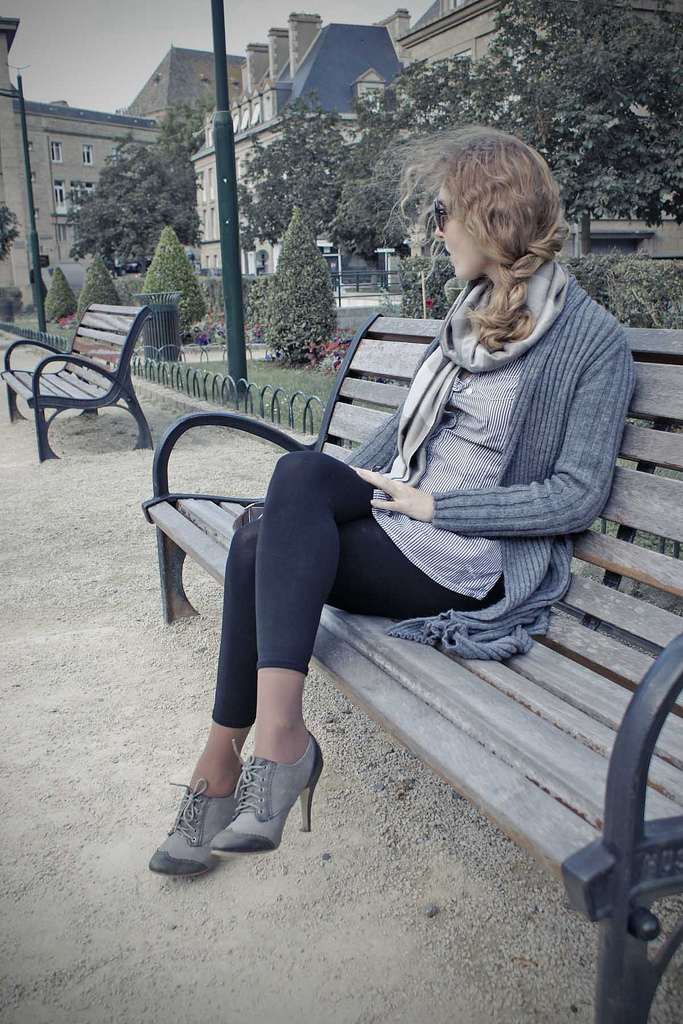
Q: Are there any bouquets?
A: No, there are no bouquets.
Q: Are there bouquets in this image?
A: No, there are no bouquets.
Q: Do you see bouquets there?
A: No, there are no bouquets.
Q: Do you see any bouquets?
A: No, there are no bouquets.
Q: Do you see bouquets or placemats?
A: No, there are no bouquets or placemats.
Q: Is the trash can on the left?
A: Yes, the trash can is on the left of the image.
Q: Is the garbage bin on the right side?
A: No, the garbage bin is on the left of the image.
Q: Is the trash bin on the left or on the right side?
A: The trash bin is on the left of the image.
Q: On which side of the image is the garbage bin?
A: The garbage bin is on the left of the image.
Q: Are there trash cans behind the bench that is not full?
A: Yes, there is a trash can behind the bench.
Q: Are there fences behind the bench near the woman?
A: No, there is a trash can behind the bench.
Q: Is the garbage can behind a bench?
A: Yes, the garbage can is behind a bench.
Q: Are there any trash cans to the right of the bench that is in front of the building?
A: Yes, there is a trash can to the right of the bench.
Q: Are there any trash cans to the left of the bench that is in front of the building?
A: No, the trash can is to the right of the bench.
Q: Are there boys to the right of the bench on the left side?
A: No, there is a trash can to the right of the bench.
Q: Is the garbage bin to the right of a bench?
A: Yes, the garbage bin is to the right of a bench.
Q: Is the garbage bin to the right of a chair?
A: No, the garbage bin is to the right of a bench.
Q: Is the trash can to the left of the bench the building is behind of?
A: No, the trash can is to the right of the bench.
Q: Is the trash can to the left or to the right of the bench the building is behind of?
A: The trash can is to the right of the bench.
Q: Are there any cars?
A: No, there are no cars.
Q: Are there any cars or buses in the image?
A: No, there are no cars or buses.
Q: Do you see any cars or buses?
A: No, there are no cars or buses.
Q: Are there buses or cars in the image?
A: No, there are no cars or buses.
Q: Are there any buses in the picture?
A: No, there are no buses.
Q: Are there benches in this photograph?
A: Yes, there is a bench.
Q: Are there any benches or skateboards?
A: Yes, there is a bench.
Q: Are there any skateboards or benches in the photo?
A: Yes, there is a bench.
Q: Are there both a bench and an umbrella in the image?
A: No, there is a bench but no umbrellas.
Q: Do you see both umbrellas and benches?
A: No, there is a bench but no umbrellas.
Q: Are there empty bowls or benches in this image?
A: Yes, there is an empty bench.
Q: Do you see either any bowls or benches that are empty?
A: Yes, the bench is empty.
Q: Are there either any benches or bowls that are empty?
A: Yes, the bench is empty.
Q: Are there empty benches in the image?
A: Yes, there is an empty bench.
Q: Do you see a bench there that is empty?
A: Yes, there is a bench that is empty.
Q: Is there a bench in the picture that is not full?
A: Yes, there is a empty bench.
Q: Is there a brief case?
A: No, there are no briefcases.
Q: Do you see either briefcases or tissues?
A: No, there are no briefcases or tissues.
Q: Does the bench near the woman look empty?
A: Yes, the bench is empty.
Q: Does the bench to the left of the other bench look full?
A: No, the bench is empty.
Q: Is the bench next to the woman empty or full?
A: The bench is empty.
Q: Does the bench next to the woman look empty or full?
A: The bench is empty.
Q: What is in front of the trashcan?
A: The bench is in front of the trashcan.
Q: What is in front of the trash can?
A: The bench is in front of the trashcan.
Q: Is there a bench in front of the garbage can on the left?
A: Yes, there is a bench in front of the trash can.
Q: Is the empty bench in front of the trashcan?
A: Yes, the bench is in front of the trashcan.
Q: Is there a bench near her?
A: Yes, there is a bench near the woman.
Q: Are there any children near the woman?
A: No, there is a bench near the woman.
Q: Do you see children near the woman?
A: No, there is a bench near the woman.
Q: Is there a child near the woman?
A: No, there is a bench near the woman.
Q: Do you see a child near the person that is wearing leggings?
A: No, there is a bench near the woman.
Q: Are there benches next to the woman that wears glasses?
A: Yes, there is a bench next to the woman.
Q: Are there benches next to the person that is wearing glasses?
A: Yes, there is a bench next to the woman.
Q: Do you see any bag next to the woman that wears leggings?
A: No, there is a bench next to the woman.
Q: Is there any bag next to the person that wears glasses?
A: No, there is a bench next to the woman.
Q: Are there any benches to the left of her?
A: Yes, there is a bench to the left of the woman.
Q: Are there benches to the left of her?
A: Yes, there is a bench to the left of the woman.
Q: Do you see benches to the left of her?
A: Yes, there is a bench to the left of the woman.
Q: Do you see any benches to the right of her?
A: No, the bench is to the left of the woman.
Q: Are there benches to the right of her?
A: No, the bench is to the left of the woman.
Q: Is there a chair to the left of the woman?
A: No, there is a bench to the left of the woman.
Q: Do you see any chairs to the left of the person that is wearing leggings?
A: No, there is a bench to the left of the woman.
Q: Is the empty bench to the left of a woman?
A: Yes, the bench is to the left of a woman.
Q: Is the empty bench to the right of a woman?
A: No, the bench is to the left of a woman.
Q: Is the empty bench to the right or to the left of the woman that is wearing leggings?
A: The bench is to the left of the woman.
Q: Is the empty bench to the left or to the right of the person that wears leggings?
A: The bench is to the left of the woman.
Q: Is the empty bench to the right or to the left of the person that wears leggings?
A: The bench is to the left of the woman.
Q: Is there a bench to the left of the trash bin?
A: Yes, there is a bench to the left of the trash bin.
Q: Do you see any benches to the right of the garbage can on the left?
A: No, the bench is to the left of the trashcan.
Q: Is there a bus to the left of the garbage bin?
A: No, there is a bench to the left of the garbage bin.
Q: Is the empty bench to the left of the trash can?
A: Yes, the bench is to the left of the trash can.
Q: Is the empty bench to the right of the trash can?
A: No, the bench is to the left of the trash can.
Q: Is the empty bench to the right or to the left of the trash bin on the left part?
A: The bench is to the left of the trash bin.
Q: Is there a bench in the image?
A: Yes, there is a bench.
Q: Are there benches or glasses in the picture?
A: Yes, there is a bench.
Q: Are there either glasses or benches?
A: Yes, there is a bench.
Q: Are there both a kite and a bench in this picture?
A: No, there is a bench but no kites.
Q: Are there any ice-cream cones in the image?
A: No, there are no ice-cream cones.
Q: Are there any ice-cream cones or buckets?
A: No, there are no ice-cream cones or buckets.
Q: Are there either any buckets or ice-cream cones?
A: No, there are no ice-cream cones or buckets.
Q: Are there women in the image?
A: Yes, there is a woman.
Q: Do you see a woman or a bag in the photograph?
A: Yes, there is a woman.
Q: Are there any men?
A: No, there are no men.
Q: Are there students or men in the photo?
A: No, there are no men or students.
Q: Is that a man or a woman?
A: That is a woman.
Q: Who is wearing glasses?
A: The woman is wearing glasses.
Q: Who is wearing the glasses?
A: The woman is wearing glasses.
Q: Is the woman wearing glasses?
A: Yes, the woman is wearing glasses.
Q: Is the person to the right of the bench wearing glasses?
A: Yes, the woman is wearing glasses.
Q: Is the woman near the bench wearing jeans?
A: No, the woman is wearing glasses.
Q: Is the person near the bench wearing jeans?
A: No, the woman is wearing glasses.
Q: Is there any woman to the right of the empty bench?
A: Yes, there is a woman to the right of the bench.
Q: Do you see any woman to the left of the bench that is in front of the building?
A: No, the woman is to the right of the bench.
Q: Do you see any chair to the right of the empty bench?
A: No, there is a woman to the right of the bench.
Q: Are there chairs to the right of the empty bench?
A: No, there is a woman to the right of the bench.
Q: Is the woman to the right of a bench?
A: Yes, the woman is to the right of a bench.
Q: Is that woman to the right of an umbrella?
A: No, the woman is to the right of a bench.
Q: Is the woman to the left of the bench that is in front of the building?
A: No, the woman is to the right of the bench.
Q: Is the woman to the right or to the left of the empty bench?
A: The woman is to the right of the bench.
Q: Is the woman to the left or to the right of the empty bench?
A: The woman is to the right of the bench.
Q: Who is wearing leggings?
A: The woman is wearing leggings.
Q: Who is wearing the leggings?
A: The woman is wearing leggings.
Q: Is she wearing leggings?
A: Yes, the woman is wearing leggings.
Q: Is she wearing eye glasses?
A: No, the woman is wearing leggings.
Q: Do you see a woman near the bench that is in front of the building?
A: Yes, there is a woman near the bench.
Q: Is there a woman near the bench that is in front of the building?
A: Yes, there is a woman near the bench.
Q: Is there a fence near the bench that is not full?
A: No, there is a woman near the bench.